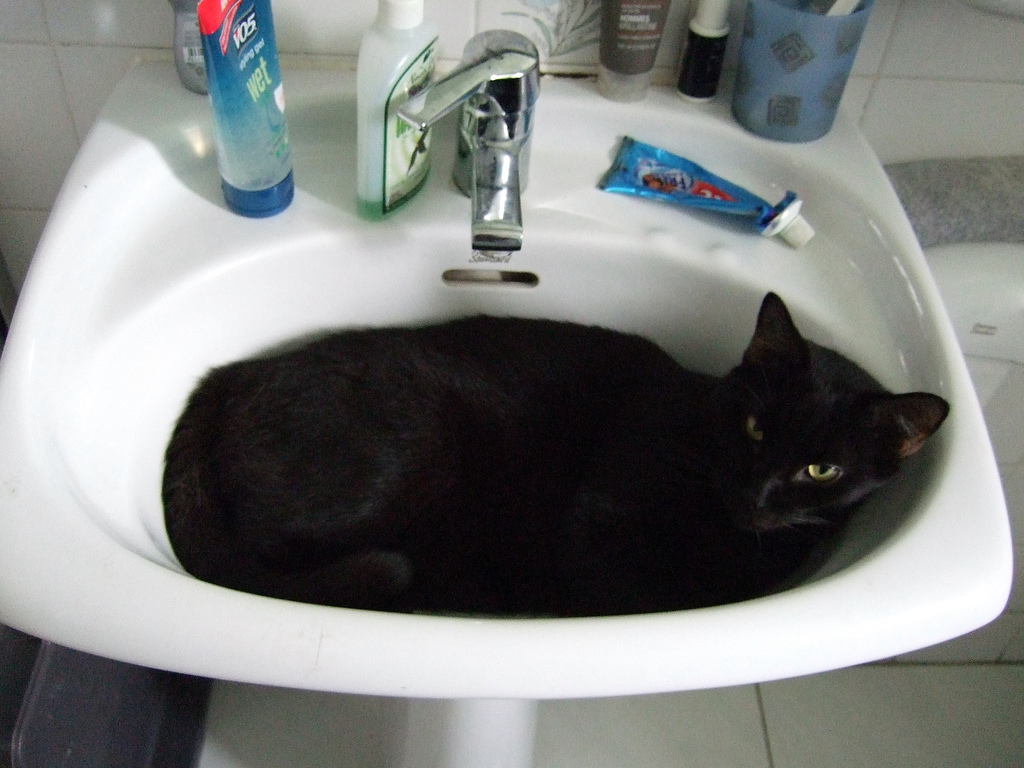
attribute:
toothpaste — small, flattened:
[595, 131, 817, 248]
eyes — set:
[732, 412, 847, 488]